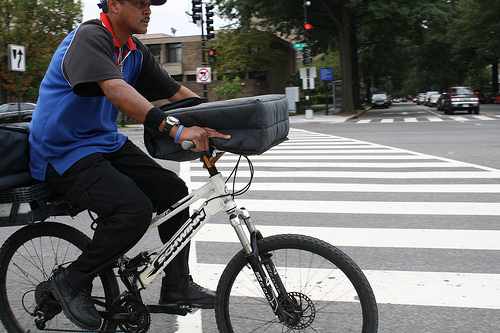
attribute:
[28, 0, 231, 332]
man — delivery man, pizza delivery man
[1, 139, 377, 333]
bike — black, white, a schwinn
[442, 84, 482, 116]
car — stopped, truck, red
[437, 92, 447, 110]
car — stopped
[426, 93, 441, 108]
car — stopped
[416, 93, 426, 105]
car — stopped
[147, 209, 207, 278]
logo — "schwinn"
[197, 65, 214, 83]
sign — no left turn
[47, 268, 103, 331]
shoe — black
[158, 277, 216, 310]
shoe — black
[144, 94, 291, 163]
pizza pouch — black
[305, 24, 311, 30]
light — red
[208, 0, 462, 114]
tree — green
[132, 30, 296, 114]
building — brick, brown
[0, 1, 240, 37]
sky — grayish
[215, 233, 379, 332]
tire — front tire, black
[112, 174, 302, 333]
frame — white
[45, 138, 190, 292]
pants — black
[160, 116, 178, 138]
watch — black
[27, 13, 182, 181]
shirt — blue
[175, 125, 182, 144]
wristband — blue